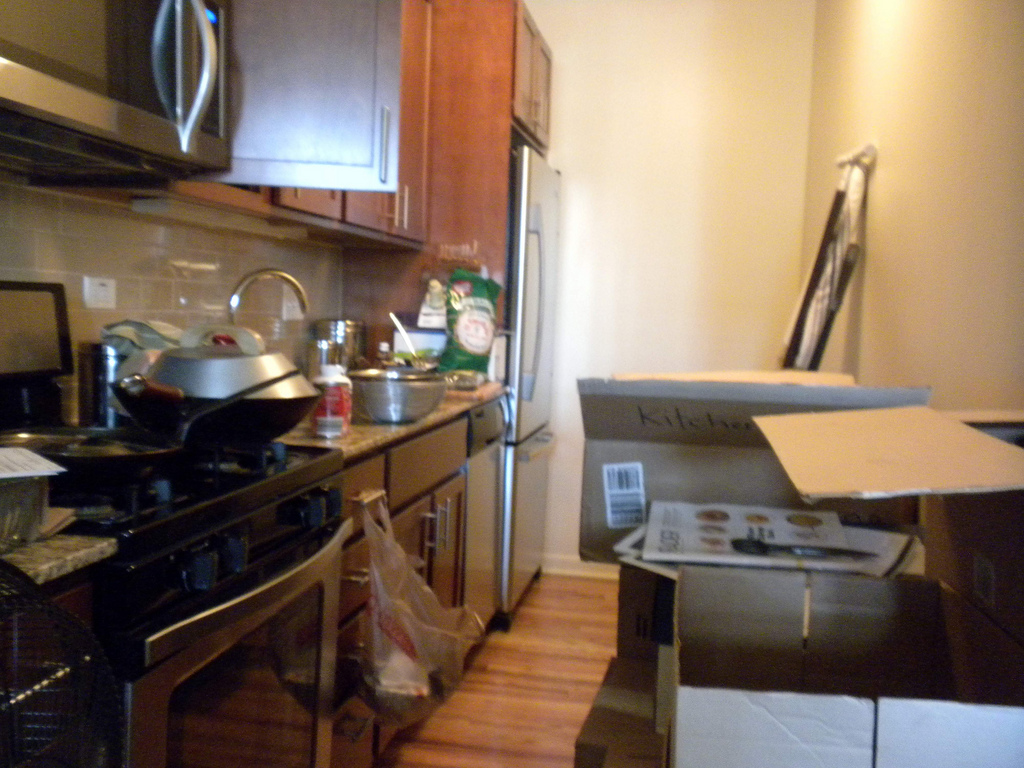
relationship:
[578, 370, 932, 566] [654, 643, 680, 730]
box on counter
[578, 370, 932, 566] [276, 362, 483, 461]
box on counter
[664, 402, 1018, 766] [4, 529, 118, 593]
box on counter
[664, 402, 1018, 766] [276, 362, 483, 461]
box on counter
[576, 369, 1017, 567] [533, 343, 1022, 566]
box on counter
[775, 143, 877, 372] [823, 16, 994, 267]
object propped against wall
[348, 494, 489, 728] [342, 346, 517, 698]
bag hanging on handle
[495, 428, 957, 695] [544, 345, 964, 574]
box on top of a box